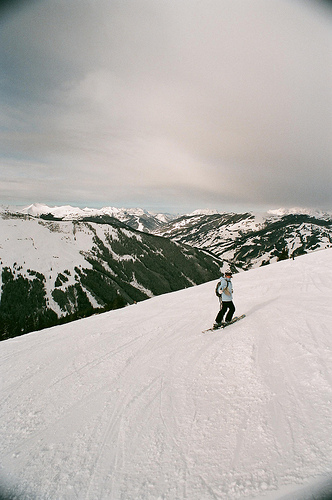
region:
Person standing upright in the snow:
[213, 270, 235, 328]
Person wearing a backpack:
[212, 270, 237, 328]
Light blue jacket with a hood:
[219, 276, 236, 300]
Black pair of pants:
[214, 299, 234, 326]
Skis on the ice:
[199, 313, 248, 333]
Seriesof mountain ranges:
[0, 205, 331, 344]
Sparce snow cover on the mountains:
[1, 212, 331, 349]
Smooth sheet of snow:
[0, 247, 331, 498]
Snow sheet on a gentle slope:
[0, 247, 331, 499]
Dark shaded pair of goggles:
[225, 271, 230, 277]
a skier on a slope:
[198, 262, 250, 335]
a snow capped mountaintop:
[22, 198, 45, 212]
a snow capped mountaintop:
[54, 201, 77, 214]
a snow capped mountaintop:
[81, 203, 93, 213]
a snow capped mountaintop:
[103, 199, 119, 214]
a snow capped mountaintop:
[154, 209, 169, 220]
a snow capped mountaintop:
[184, 204, 217, 213]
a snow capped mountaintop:
[266, 205, 330, 218]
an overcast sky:
[12, 5, 328, 180]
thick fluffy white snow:
[17, 349, 312, 478]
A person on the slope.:
[193, 239, 242, 334]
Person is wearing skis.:
[199, 321, 243, 331]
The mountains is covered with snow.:
[14, 202, 268, 274]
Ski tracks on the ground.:
[54, 355, 324, 440]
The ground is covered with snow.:
[47, 361, 300, 448]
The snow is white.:
[62, 384, 307, 471]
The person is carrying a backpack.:
[217, 278, 232, 295]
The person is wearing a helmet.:
[220, 265, 236, 273]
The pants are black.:
[208, 301, 251, 320]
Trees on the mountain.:
[4, 286, 43, 331]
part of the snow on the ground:
[290, 459, 312, 490]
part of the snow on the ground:
[225, 458, 253, 496]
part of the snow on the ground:
[150, 462, 192, 498]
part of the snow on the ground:
[65, 451, 104, 497]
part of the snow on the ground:
[7, 415, 47, 463]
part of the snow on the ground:
[81, 386, 125, 420]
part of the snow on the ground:
[169, 384, 228, 429]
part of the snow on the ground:
[267, 382, 303, 406]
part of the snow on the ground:
[289, 312, 314, 340]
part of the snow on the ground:
[146, 312, 176, 356]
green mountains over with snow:
[0, 205, 331, 343]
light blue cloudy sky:
[1, 6, 329, 207]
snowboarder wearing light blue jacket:
[209, 266, 230, 324]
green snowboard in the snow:
[206, 312, 245, 331]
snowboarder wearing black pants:
[214, 268, 231, 326]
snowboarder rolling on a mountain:
[214, 263, 234, 326]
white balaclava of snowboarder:
[222, 267, 230, 277]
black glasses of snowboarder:
[223, 269, 228, 275]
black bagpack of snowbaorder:
[214, 277, 221, 295]